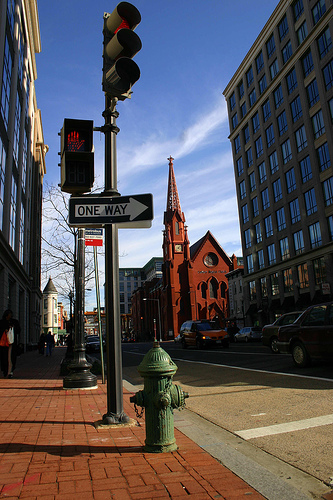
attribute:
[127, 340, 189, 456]
fire hydrant — green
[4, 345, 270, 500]
sidewalk — red, brick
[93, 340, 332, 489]
lines — white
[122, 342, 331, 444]
lines — white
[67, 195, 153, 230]
sign — white, black, one way sign, one way, street sign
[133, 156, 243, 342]
church — red, brick, large, orange, tall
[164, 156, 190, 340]
tower — tall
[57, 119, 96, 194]
indicator — cross walk, red, do not walk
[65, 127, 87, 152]
hand signal — orange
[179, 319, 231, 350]
van — orange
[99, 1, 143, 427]
traffic light — red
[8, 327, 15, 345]
bag — red, white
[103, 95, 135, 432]
pole — black